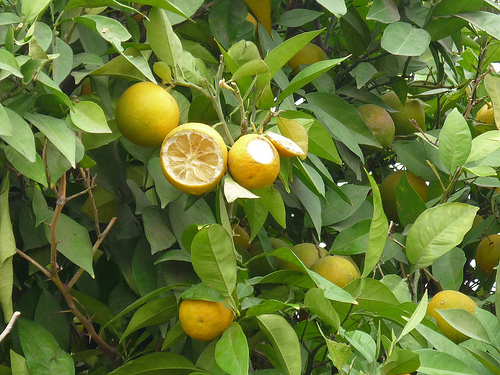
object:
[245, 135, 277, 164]
part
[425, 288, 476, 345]
lemon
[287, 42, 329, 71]
lemons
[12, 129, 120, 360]
branch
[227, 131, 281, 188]
fruit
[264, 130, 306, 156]
peel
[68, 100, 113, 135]
leaves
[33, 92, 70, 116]
leaves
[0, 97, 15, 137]
leaves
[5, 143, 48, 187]
leaves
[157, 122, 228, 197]
snowboarder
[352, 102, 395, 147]
lemons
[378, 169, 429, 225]
lemons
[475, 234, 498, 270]
lemons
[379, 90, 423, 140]
lemons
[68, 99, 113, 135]
leaf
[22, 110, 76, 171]
leaf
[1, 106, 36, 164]
leaf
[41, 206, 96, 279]
leaf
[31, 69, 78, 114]
leaf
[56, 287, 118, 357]
twig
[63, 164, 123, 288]
twig branch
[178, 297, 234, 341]
lemon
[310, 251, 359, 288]
lemon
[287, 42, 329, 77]
lemon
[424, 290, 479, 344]
lemons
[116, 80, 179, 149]
fruit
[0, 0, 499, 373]
lemon tree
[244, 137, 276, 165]
rind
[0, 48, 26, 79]
leaves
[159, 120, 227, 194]
chunk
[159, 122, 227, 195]
citrus fruit